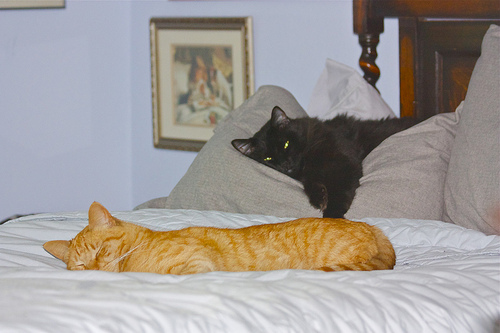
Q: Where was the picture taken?
A: A bedroom.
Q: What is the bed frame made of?
A: Wood.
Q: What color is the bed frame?
A: Brown.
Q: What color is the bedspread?
A: White.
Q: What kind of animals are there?
A: Cats.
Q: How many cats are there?
A: Two.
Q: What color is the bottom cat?
A: Orange.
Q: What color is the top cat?
A: Black.